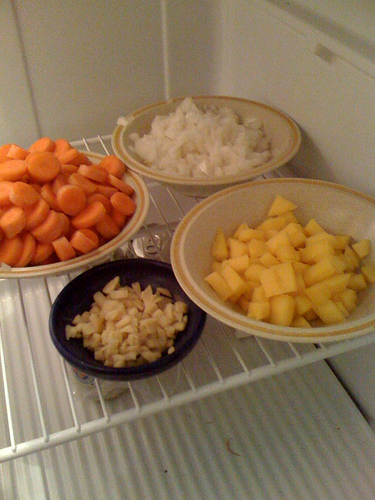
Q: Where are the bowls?
A: On rack.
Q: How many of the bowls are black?
A: One.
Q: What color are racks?
A: White.